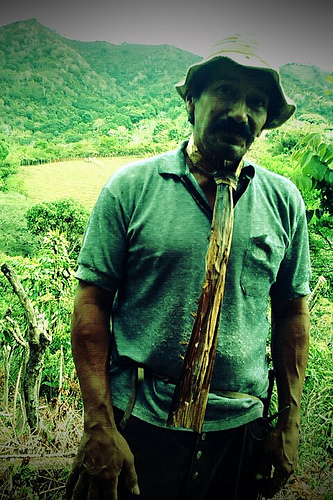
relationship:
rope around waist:
[113, 351, 260, 426] [106, 334, 273, 420]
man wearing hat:
[64, 31, 310, 498] [145, 43, 289, 120]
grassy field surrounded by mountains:
[18, 154, 152, 206] [0, 17, 332, 152]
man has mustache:
[64, 31, 322, 498] [210, 118, 254, 145]